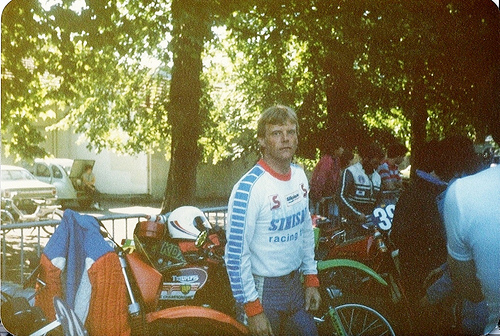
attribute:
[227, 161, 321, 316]
shirt — long-sleeve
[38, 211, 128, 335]
jacket — red, white, blue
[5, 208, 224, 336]
motorcycle — parked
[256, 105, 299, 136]
hair — short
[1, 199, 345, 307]
barrier — metal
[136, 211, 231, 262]
motorcycle — parked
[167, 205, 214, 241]
helmet — white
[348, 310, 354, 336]
spoke — metal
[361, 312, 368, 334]
spoke — metal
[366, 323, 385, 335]
spoke — metal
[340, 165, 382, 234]
jacket — white, black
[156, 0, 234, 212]
tree — leafy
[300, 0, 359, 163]
tree — leafy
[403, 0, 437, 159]
tree — leafy